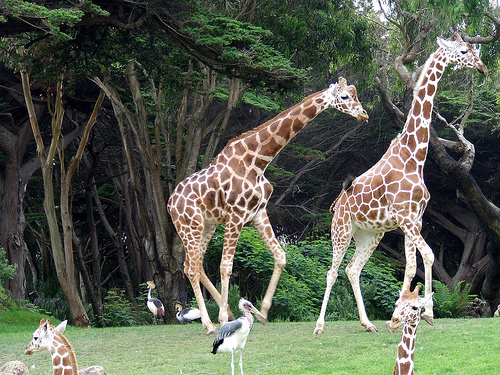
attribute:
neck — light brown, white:
[49, 337, 80, 373]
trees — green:
[8, 4, 165, 324]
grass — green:
[305, 330, 370, 367]